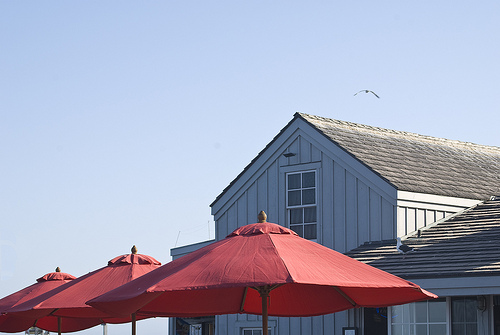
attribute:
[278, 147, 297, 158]
seabird — parked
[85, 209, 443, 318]
umbrella — red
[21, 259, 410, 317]
umbrella — red, three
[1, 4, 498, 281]
sky — clear sky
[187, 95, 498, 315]
building — gray, white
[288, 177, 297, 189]
pane — of glass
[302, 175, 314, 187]
pane — of glass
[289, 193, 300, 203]
pane — of glass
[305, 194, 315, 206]
pane — of glass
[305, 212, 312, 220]
pane — of glass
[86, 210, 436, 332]
red umbrellas — deep-red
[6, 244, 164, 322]
red umbrellas — deep-red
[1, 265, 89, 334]
red umbrellas — deep-red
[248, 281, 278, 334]
pole — wooden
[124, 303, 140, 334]
pole — wooden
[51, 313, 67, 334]
pole — wooden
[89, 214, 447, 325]
umbrella — red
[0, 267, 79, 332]
umbrella — red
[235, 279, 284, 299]
assembly — rib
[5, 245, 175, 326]
umbrella — red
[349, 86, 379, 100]
bird — flying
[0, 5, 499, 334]
sky — blue, clear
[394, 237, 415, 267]
seagull — standing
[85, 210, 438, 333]
umbrella — red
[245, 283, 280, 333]
pole — brown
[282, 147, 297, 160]
light — small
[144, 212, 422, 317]
patio umbrella — triangular-shaped, conical-shaped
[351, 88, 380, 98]
bird — above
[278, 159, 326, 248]
frame — white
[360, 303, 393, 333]
window — screen window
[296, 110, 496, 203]
roof — grey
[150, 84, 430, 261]
roof — pointed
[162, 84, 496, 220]
exterior — grey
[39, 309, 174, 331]
poles — brown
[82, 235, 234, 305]
panel — slightly-squared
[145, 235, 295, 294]
panel — slightly-squared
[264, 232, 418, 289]
panel — slightly-squared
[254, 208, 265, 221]
top — brown, wooden, final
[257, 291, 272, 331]
pole — brown-colored